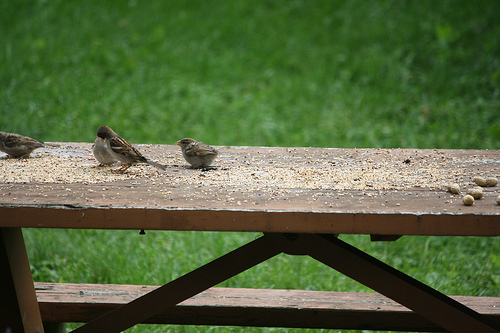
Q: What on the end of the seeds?
A: Four peanuts.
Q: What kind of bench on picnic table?
A: Wooden bench.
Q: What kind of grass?
A: Tall green grass.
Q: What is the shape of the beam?
A: X shape.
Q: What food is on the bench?
A: Bird seed.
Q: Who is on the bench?
A: Birds.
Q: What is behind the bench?
A: Grass.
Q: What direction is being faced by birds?
A: Left.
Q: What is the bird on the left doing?
A: Eating.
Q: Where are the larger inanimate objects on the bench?
A: Right end.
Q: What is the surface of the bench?
A: Wood.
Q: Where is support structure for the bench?
A: Below the surface.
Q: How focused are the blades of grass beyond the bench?
A: Blurry.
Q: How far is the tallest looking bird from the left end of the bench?
A: Third bird from the left.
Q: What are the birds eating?
A: Seed.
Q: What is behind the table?
A: Green grass.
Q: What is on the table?
A: Birds.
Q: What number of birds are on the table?
A: Four.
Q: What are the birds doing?
A: Eating.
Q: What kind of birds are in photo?
A: Finches.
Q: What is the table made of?
A: Fence.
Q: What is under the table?
A: Wooden bar.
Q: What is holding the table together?
A: Nails.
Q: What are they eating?
A: Bird seed.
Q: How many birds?
A: 4.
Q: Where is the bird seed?
A: On the fence.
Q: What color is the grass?
A: Green.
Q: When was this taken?
A: Daytime.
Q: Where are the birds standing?
A: On the bench.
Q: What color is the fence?
A: Brown.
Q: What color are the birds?
A: Brown.